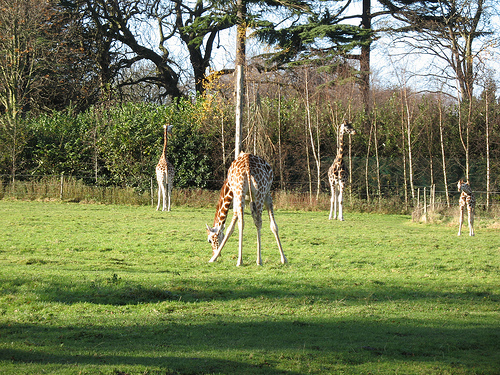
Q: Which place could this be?
A: It is a field.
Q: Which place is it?
A: It is a field.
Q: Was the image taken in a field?
A: Yes, it was taken in a field.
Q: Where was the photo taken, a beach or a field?
A: It was taken at a field.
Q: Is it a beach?
A: No, it is a field.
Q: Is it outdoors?
A: Yes, it is outdoors.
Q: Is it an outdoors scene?
A: Yes, it is outdoors.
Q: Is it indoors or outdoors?
A: It is outdoors.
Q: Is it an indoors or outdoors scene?
A: It is outdoors.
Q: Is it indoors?
A: No, it is outdoors.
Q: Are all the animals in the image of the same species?
A: Yes, all the animals are giraffes.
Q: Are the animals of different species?
A: No, all the animals are giraffes.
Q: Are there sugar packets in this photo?
A: No, there are no sugar packets.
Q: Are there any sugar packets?
A: No, there are no sugar packets.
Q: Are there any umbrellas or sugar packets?
A: No, there are no sugar packets or umbrellas.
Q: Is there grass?
A: Yes, there is grass.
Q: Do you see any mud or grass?
A: Yes, there is grass.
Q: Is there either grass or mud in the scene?
A: Yes, there is grass.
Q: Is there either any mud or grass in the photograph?
A: Yes, there is grass.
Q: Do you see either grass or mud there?
A: Yes, there is grass.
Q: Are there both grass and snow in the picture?
A: No, there is grass but no snow.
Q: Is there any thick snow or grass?
A: Yes, there is thick grass.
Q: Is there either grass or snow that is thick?
A: Yes, the grass is thick.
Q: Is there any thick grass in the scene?
A: Yes, there is thick grass.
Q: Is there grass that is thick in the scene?
A: Yes, there is thick grass.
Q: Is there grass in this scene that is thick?
A: Yes, there is grass that is thick.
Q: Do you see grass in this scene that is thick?
A: Yes, there is grass that is thick.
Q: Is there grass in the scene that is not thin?
A: Yes, there is thick grass.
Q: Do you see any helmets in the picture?
A: No, there are no helmets.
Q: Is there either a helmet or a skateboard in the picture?
A: No, there are no helmets or skateboards.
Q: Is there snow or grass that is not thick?
A: No, there is grass but it is thick.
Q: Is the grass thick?
A: Yes, the grass is thick.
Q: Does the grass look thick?
A: Yes, the grass is thick.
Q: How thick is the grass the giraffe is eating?
A: The grass is thick.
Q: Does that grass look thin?
A: No, the grass is thick.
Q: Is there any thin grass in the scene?
A: No, there is grass but it is thick.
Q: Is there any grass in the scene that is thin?
A: No, there is grass but it is thick.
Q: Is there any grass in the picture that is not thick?
A: No, there is grass but it is thick.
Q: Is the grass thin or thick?
A: The grass is thick.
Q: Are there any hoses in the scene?
A: No, there are no hoses.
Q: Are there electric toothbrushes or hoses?
A: No, there are no hoses or electric toothbrushes.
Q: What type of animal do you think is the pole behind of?
A: The pole is behind the giraffes.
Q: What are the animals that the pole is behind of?
A: The animals are giraffes.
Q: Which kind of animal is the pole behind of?
A: The pole is behind the giraffes.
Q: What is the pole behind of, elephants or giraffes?
A: The pole is behind giraffes.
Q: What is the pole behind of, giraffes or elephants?
A: The pole is behind giraffes.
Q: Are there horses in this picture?
A: No, there are no horses.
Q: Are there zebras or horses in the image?
A: No, there are no horses or zebras.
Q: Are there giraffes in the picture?
A: Yes, there is a giraffe.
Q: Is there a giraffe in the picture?
A: Yes, there is a giraffe.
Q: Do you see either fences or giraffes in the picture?
A: Yes, there is a giraffe.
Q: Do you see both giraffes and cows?
A: No, there is a giraffe but no cows.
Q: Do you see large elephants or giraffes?
A: Yes, there is a large giraffe.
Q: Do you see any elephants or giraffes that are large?
A: Yes, the giraffe is large.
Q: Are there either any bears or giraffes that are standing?
A: Yes, the giraffe is standing.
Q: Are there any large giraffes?
A: Yes, there is a large giraffe.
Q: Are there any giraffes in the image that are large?
A: Yes, there is a giraffe that is large.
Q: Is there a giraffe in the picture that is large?
A: Yes, there is a giraffe that is large.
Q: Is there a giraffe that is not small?
A: Yes, there is a large giraffe.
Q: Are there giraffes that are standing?
A: Yes, there is a giraffe that is standing.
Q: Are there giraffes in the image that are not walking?
A: Yes, there is a giraffe that is standing.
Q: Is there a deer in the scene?
A: No, there is no deer.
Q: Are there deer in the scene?
A: No, there are no deer.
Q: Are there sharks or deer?
A: No, there are no deer or sharks.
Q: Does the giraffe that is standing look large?
A: Yes, the giraffe is large.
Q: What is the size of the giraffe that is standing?
A: The giraffe is large.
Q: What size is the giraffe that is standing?
A: The giraffe is large.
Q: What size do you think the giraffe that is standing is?
A: The giraffe is large.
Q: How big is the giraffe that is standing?
A: The giraffe is large.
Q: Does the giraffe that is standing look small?
A: No, the giraffe is large.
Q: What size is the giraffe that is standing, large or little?
A: The giraffe is large.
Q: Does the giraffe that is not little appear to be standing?
A: Yes, the giraffe is standing.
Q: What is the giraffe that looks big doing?
A: The giraffe is standing.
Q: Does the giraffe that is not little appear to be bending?
A: No, the giraffe is standing.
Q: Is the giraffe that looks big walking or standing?
A: The giraffe is standing.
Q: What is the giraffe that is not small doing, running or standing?
A: The giraffe is standing.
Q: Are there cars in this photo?
A: No, there are no cars.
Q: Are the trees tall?
A: Yes, the trees are tall.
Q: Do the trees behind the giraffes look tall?
A: Yes, the trees are tall.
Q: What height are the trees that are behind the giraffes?
A: The trees are tall.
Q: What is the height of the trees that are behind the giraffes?
A: The trees are tall.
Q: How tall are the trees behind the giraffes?
A: The trees are tall.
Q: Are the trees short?
A: No, the trees are tall.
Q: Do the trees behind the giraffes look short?
A: No, the trees are tall.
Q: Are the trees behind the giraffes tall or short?
A: The trees are tall.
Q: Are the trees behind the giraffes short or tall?
A: The trees are tall.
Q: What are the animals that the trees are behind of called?
A: The animals are giraffes.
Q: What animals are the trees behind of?
A: The trees are behind the giraffes.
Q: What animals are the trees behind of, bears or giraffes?
A: The trees are behind giraffes.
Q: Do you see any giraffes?
A: Yes, there are giraffes.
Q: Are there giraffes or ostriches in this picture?
A: Yes, there are giraffes.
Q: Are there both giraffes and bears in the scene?
A: No, there are giraffes but no bears.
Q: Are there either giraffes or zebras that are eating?
A: Yes, the giraffes are eating.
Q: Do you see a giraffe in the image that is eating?
A: Yes, there are giraffes that are eating.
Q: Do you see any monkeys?
A: No, there are no monkeys.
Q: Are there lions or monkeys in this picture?
A: No, there are no monkeys or lions.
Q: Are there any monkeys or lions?
A: No, there are no monkeys or lions.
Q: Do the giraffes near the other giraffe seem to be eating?
A: Yes, the giraffes are eating.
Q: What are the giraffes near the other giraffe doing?
A: The giraffes are eating.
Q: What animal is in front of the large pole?
A: The giraffes are in front of the pole.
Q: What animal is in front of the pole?
A: The giraffes are in front of the pole.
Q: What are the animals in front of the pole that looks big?
A: The animals are giraffes.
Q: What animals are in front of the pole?
A: The animals are giraffes.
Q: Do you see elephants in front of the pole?
A: No, there are giraffes in front of the pole.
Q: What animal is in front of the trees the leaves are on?
A: The giraffes are in front of the trees.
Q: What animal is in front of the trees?
A: The giraffes are in front of the trees.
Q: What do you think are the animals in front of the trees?
A: The animals are giraffes.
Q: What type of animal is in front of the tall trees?
A: The animals are giraffes.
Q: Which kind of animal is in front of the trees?
A: The animals are giraffes.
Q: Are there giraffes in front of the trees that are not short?
A: Yes, there are giraffes in front of the trees.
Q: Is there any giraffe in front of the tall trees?
A: Yes, there are giraffes in front of the trees.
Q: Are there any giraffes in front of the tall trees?
A: Yes, there are giraffes in front of the trees.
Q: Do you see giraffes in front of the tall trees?
A: Yes, there are giraffes in front of the trees.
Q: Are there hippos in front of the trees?
A: No, there are giraffes in front of the trees.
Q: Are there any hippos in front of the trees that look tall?
A: No, there are giraffes in front of the trees.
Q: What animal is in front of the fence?
A: The giraffes are in front of the fence.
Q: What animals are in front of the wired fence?
A: The animals are giraffes.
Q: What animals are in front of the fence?
A: The animals are giraffes.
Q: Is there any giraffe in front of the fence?
A: Yes, there are giraffes in front of the fence.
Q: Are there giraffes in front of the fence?
A: Yes, there are giraffes in front of the fence.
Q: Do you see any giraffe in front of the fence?
A: Yes, there are giraffes in front of the fence.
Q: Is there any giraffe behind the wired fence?
A: No, the giraffes are in front of the fence.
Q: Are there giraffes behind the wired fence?
A: No, the giraffes are in front of the fence.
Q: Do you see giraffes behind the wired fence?
A: No, the giraffes are in front of the fence.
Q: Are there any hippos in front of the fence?
A: No, there are giraffes in front of the fence.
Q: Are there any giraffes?
A: Yes, there is a giraffe.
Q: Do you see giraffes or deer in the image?
A: Yes, there is a giraffe.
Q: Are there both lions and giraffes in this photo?
A: No, there is a giraffe but no lions.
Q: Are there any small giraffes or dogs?
A: Yes, there is a small giraffe.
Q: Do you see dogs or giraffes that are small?
A: Yes, the giraffe is small.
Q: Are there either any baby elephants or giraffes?
A: Yes, there is a baby giraffe.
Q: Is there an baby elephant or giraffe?
A: Yes, there is a baby giraffe.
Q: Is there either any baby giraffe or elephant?
A: Yes, there is a baby giraffe.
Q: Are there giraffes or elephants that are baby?
A: Yes, the giraffe is a baby.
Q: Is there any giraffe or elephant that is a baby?
A: Yes, the giraffe is a baby.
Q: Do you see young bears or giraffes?
A: Yes, there is a young giraffe.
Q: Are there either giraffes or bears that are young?
A: Yes, the giraffe is young.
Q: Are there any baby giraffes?
A: Yes, there is a baby giraffe.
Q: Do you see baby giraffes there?
A: Yes, there is a baby giraffe.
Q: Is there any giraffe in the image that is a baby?
A: Yes, there is a giraffe that is a baby.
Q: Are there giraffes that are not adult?
A: Yes, there is an baby giraffe.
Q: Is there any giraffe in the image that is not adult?
A: Yes, there is an baby giraffe.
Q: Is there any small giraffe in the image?
A: Yes, there is a small giraffe.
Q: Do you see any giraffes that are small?
A: Yes, there is a giraffe that is small.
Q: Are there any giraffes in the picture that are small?
A: Yes, there is a giraffe that is small.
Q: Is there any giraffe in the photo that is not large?
A: Yes, there is a small giraffe.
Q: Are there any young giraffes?
A: Yes, there is a young giraffe.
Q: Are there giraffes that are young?
A: Yes, there is a giraffe that is young.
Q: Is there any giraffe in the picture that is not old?
A: Yes, there is an young giraffe.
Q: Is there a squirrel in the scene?
A: No, there are no squirrels.